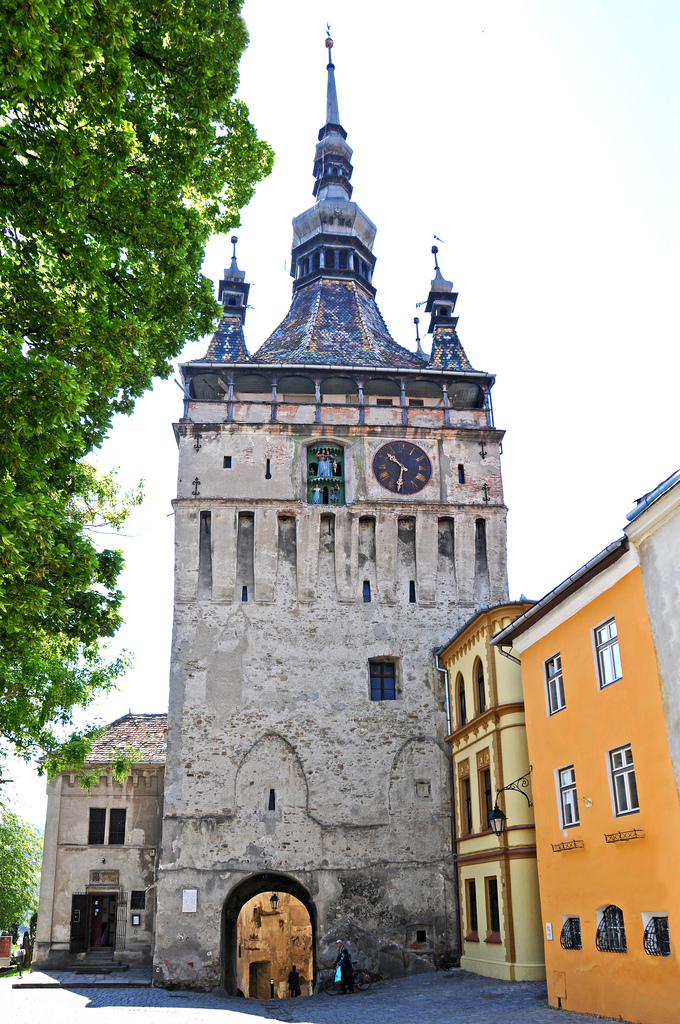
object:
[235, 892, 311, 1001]
wall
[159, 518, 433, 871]
wall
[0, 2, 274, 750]
leaves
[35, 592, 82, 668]
leaves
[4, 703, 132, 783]
leaves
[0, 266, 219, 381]
leaves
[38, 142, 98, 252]
leaves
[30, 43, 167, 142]
leaves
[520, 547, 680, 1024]
yellow building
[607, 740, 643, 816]
windows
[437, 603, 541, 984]
building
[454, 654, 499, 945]
windows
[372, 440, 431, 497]
clock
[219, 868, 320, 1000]
archway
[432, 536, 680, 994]
building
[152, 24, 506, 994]
tower